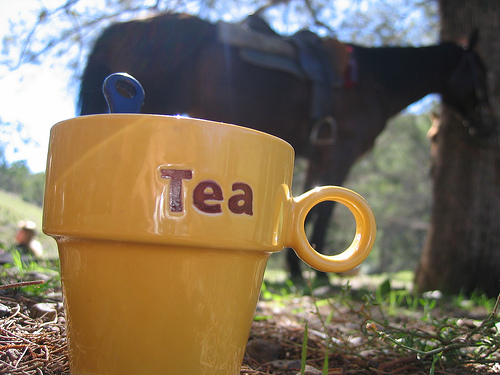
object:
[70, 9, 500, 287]
horse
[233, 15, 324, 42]
saddle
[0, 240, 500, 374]
grass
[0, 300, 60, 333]
bundle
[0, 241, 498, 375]
ground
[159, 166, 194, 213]
letters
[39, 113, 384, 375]
pot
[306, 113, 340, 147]
stirrup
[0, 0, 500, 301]
tree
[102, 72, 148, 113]
handle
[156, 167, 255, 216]
tea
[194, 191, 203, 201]
red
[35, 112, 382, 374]
mug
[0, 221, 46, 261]
person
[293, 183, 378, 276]
handle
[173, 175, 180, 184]
brown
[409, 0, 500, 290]
trunk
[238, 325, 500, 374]
weeds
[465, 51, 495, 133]
bridle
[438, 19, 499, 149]
head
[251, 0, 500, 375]
right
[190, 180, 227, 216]
letter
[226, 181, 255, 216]
letter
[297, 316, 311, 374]
plant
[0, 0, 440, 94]
edge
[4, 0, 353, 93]
part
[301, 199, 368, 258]
edge